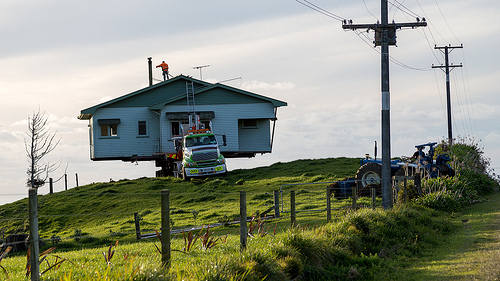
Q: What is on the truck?
A: A house.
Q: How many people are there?
A: One.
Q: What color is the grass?
A: Green.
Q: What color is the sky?
A: Blue.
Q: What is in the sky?
A: Clouds.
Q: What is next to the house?
A: A tree.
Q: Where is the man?
A: On the roof.